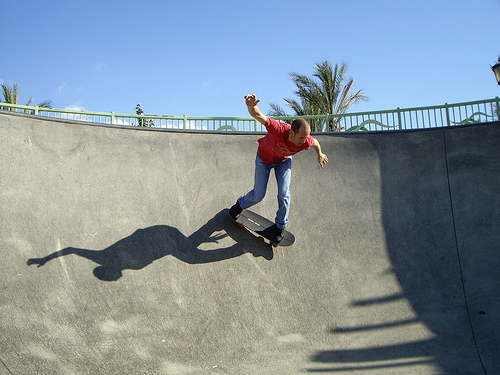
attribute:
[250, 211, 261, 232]
skate board — black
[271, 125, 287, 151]
t-shirt — red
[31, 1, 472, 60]
sky — blue, clear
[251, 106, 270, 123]
arm — extended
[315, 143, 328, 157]
arm — extended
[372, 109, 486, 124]
fence — meta, green, metal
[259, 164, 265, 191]
jeans — blue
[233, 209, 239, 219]
shoe — black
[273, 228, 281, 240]
shoe — black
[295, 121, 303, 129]
hair — short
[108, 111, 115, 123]
post — green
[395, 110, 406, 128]
post — green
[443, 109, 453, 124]
post — green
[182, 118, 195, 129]
post — green